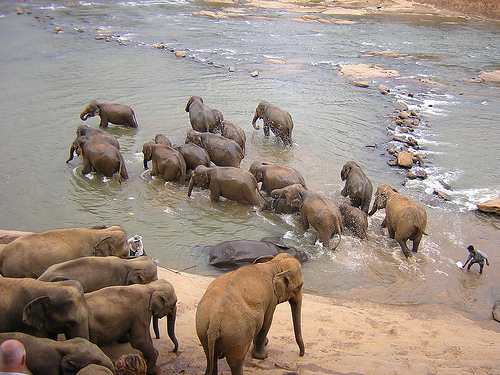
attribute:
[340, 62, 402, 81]
patch — large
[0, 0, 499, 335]
water — brown, murky, rippling, muddy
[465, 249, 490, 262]
shirt — white, long sleeved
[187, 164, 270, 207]
elephant — large, wet, brown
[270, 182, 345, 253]
elephant — large, walking, brown, wet, splashing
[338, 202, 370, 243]
elephant — small, wet, splashing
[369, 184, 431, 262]
elephant — large, walking, brown, splashing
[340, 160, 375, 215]
elephant — wet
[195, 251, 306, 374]
elephant — large, brown, standing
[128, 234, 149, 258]
man — standing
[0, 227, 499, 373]
shore — sandy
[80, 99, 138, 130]
elephant — brown, wet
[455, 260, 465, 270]
container — white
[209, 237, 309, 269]
elephant — bathing, splashing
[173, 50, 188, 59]
stone — medium sized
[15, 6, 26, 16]
stone — medium sized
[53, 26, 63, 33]
stone — medium sized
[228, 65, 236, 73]
stone — medium sized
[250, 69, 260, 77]
stone — medium sized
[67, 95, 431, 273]
group — huddled, together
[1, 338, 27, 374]
man — bald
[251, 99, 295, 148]
elephant — splashing, walking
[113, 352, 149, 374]
person — frosted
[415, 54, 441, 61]
object — dark, brown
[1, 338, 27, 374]
head — bald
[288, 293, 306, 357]
trunk — long, gray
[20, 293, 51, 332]
ear — large, gray